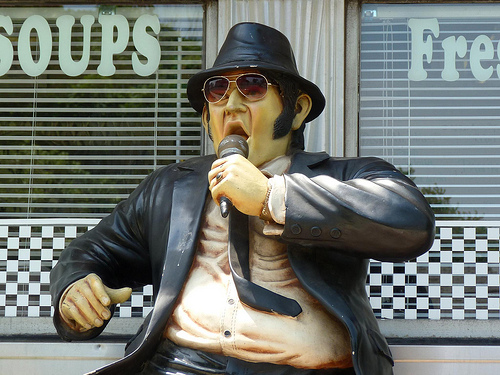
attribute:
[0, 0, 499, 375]
picture — daytime, outdoors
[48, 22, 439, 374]
statue — plastic, blues brother, like blues brother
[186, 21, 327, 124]
hat — black, blue, dark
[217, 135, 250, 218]
microphone — grey, fake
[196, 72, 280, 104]
sunglasses — dark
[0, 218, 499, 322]
tiles — black, checkered, white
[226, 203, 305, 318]
tie — black, long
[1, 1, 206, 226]
window — reflective, open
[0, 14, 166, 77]
words — white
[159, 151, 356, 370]
shirt — white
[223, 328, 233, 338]
button — black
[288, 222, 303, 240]
button — black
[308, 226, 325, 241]
button — black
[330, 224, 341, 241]
button — black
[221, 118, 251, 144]
mouth — open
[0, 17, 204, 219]
blinds — white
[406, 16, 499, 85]
words — white